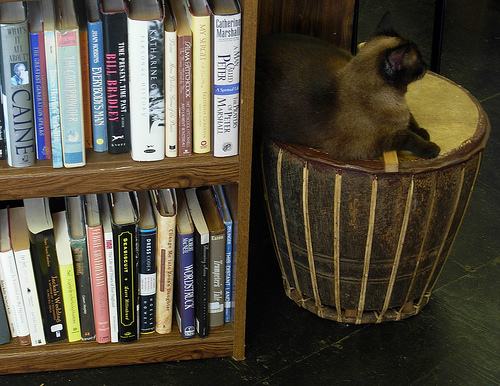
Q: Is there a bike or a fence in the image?
A: No, there are no fences or bikes.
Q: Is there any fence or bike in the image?
A: No, there are no fences or bikes.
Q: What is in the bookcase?
A: The books are in the bookcase.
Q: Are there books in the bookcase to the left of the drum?
A: Yes, there are books in the bookcase.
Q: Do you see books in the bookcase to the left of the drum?
A: Yes, there are books in the bookcase.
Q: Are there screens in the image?
A: No, there are no screens.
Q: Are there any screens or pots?
A: No, there are no screens or pots.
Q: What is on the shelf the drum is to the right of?
A: The books are on the shelf.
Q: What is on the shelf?
A: The books are on the shelf.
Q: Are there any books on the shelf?
A: Yes, there are books on the shelf.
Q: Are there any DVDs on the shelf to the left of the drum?
A: No, there are books on the shelf.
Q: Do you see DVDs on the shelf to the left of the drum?
A: No, there are books on the shelf.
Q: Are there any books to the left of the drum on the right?
A: Yes, there are books to the left of the drum.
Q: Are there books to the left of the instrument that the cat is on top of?
A: Yes, there are books to the left of the drum.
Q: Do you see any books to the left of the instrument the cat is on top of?
A: Yes, there are books to the left of the drum.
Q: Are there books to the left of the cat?
A: Yes, there are books to the left of the cat.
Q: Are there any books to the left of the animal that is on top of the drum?
A: Yes, there are books to the left of the cat.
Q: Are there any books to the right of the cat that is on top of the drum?
A: No, the books are to the left of the cat.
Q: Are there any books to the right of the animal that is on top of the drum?
A: No, the books are to the left of the cat.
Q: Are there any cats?
A: Yes, there is a cat.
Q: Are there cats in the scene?
A: Yes, there is a cat.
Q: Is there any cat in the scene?
A: Yes, there is a cat.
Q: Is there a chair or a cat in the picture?
A: Yes, there is a cat.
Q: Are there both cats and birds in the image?
A: No, there is a cat but no birds.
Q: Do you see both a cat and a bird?
A: No, there is a cat but no birds.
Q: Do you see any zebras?
A: No, there are no zebras.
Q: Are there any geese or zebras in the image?
A: No, there are no zebras or geese.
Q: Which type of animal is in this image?
A: The animal is a cat.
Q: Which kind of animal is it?
A: The animal is a cat.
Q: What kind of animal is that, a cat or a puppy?
A: This is a cat.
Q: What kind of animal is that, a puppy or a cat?
A: This is a cat.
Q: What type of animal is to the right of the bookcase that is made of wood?
A: The animal is a cat.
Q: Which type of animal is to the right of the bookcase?
A: The animal is a cat.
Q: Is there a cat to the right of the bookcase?
A: Yes, there is a cat to the right of the bookcase.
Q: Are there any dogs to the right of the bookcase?
A: No, there is a cat to the right of the bookcase.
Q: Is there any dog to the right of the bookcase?
A: No, there is a cat to the right of the bookcase.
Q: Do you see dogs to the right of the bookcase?
A: No, there is a cat to the right of the bookcase.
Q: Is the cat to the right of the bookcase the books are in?
A: Yes, the cat is to the right of the bookcase.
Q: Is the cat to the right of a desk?
A: No, the cat is to the right of the bookcase.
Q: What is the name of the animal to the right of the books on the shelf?
A: The animal is a cat.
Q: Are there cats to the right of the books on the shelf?
A: Yes, there is a cat to the right of the books.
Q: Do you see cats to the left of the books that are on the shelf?
A: No, the cat is to the right of the books.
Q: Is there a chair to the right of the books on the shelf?
A: No, there is a cat to the right of the books.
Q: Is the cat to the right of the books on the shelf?
A: Yes, the cat is to the right of the books.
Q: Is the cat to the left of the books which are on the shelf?
A: No, the cat is to the right of the books.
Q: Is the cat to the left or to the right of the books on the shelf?
A: The cat is to the right of the books.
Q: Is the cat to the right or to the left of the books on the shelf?
A: The cat is to the right of the books.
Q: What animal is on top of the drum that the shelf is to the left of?
A: The cat is on top of the drum.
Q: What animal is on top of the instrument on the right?
A: The cat is on top of the drum.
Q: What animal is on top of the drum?
A: The cat is on top of the drum.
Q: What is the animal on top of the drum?
A: The animal is a cat.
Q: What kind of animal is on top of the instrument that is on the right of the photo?
A: The animal is a cat.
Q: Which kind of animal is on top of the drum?
A: The animal is a cat.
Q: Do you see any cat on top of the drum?
A: Yes, there is a cat on top of the drum.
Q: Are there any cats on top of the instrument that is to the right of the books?
A: Yes, there is a cat on top of the drum.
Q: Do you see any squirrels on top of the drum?
A: No, there is a cat on top of the drum.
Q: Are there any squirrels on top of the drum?
A: No, there is a cat on top of the drum.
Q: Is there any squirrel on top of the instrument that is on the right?
A: No, there is a cat on top of the drum.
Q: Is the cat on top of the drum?
A: Yes, the cat is on top of the drum.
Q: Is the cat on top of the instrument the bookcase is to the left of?
A: Yes, the cat is on top of the drum.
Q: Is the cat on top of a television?
A: No, the cat is on top of the drum.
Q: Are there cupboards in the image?
A: No, there are no cupboards.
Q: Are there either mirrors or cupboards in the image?
A: No, there are no cupboards or mirrors.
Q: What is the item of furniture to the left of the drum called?
A: The piece of furniture is a shelf.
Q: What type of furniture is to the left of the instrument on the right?
A: The piece of furniture is a shelf.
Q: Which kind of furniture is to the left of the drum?
A: The piece of furniture is a shelf.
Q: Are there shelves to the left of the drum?
A: Yes, there is a shelf to the left of the drum.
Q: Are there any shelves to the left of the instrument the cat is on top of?
A: Yes, there is a shelf to the left of the drum.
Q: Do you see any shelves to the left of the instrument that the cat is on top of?
A: Yes, there is a shelf to the left of the drum.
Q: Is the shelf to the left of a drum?
A: Yes, the shelf is to the left of a drum.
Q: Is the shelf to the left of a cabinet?
A: No, the shelf is to the left of a drum.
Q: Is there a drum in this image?
A: Yes, there is a drum.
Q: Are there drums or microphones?
A: Yes, there is a drum.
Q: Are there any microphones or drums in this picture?
A: Yes, there is a drum.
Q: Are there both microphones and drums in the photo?
A: No, there is a drum but no microphones.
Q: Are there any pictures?
A: No, there are no pictures.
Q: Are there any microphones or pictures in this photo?
A: No, there are no pictures or microphones.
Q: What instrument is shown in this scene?
A: The instrument is a drum.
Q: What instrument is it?
A: The instrument is a drum.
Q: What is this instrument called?
A: This is a drum.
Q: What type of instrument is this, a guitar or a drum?
A: This is a drum.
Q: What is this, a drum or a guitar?
A: This is a drum.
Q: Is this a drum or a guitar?
A: This is a drum.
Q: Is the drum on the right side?
A: Yes, the drum is on the right of the image.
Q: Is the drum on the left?
A: No, the drum is on the right of the image.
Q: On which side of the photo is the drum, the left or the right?
A: The drum is on the right of the image.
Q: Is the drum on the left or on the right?
A: The drum is on the right of the image.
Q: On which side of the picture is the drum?
A: The drum is on the right of the image.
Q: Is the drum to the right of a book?
A: Yes, the drum is to the right of a book.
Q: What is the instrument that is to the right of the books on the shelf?
A: The instrument is a drum.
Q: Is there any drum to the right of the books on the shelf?
A: Yes, there is a drum to the right of the books.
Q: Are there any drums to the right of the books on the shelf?
A: Yes, there is a drum to the right of the books.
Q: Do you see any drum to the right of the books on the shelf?
A: Yes, there is a drum to the right of the books.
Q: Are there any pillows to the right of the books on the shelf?
A: No, there is a drum to the right of the books.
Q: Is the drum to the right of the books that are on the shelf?
A: Yes, the drum is to the right of the books.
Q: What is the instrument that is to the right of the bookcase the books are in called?
A: The instrument is a drum.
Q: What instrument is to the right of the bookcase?
A: The instrument is a drum.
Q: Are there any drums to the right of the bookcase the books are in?
A: Yes, there is a drum to the right of the bookcase.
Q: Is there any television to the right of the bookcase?
A: No, there is a drum to the right of the bookcase.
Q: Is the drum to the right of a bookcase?
A: Yes, the drum is to the right of a bookcase.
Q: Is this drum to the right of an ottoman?
A: No, the drum is to the right of a bookcase.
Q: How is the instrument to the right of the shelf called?
A: The instrument is a drum.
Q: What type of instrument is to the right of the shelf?
A: The instrument is a drum.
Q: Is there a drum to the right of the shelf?
A: Yes, there is a drum to the right of the shelf.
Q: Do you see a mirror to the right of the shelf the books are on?
A: No, there is a drum to the right of the shelf.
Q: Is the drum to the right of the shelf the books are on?
A: Yes, the drum is to the right of the shelf.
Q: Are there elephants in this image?
A: No, there are no elephants.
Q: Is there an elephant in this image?
A: No, there are no elephants.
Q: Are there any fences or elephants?
A: No, there are no elephants or fences.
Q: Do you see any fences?
A: No, there are no fences.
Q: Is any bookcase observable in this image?
A: Yes, there is a bookcase.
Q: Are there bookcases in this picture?
A: Yes, there is a bookcase.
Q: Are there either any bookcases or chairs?
A: Yes, there is a bookcase.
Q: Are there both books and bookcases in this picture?
A: Yes, there are both a bookcase and books.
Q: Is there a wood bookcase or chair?
A: Yes, there is a wood bookcase.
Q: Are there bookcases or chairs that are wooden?
A: Yes, the bookcase is wooden.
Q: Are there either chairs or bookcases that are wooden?
A: Yes, the bookcase is wooden.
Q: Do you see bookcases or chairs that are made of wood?
A: Yes, the bookcase is made of wood.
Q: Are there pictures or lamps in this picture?
A: No, there are no pictures or lamps.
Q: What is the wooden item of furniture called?
A: The piece of furniture is a bookcase.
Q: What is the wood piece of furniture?
A: The piece of furniture is a bookcase.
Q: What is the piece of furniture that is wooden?
A: The piece of furniture is a bookcase.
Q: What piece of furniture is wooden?
A: The piece of furniture is a bookcase.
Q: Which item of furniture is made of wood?
A: The piece of furniture is a bookcase.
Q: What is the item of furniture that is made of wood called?
A: The piece of furniture is a bookcase.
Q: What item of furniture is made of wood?
A: The piece of furniture is a bookcase.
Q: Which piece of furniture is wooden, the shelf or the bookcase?
A: The bookcase is wooden.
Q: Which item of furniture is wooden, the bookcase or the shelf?
A: The bookcase is wooden.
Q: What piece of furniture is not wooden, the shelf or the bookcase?
A: The shelf is not wooden.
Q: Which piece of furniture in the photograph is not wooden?
A: The piece of furniture is a shelf.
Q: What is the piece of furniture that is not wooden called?
A: The piece of furniture is a shelf.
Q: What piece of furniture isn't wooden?
A: The piece of furniture is a shelf.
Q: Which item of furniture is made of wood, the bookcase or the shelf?
A: The bookcase is made of wood.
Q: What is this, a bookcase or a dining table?
A: This is a bookcase.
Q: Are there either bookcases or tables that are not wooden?
A: No, there is a bookcase but it is wooden.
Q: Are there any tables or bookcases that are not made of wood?
A: No, there is a bookcase but it is made of wood.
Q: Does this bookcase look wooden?
A: Yes, the bookcase is wooden.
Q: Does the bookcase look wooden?
A: Yes, the bookcase is wooden.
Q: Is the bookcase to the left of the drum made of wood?
A: Yes, the bookcase is made of wood.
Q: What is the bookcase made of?
A: The bookcase is made of wood.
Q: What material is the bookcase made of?
A: The bookcase is made of wood.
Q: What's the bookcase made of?
A: The bookcase is made of wood.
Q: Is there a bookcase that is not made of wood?
A: No, there is a bookcase but it is made of wood.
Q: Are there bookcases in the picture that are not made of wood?
A: No, there is a bookcase but it is made of wood.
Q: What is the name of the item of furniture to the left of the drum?
A: The piece of furniture is a bookcase.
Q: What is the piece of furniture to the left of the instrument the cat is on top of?
A: The piece of furniture is a bookcase.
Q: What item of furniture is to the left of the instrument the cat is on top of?
A: The piece of furniture is a bookcase.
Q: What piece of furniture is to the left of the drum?
A: The piece of furniture is a bookcase.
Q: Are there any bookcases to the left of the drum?
A: Yes, there is a bookcase to the left of the drum.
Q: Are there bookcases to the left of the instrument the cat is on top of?
A: Yes, there is a bookcase to the left of the drum.